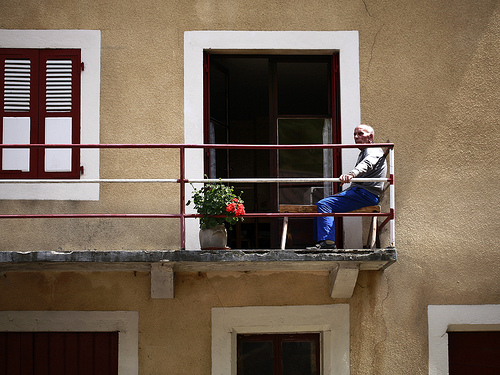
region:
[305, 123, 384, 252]
a seated mean in blue pants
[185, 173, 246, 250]
a potted plant with red flowers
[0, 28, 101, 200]
a red and white window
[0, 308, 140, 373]
the top corner of a door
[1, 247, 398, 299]
the floor of a balcony with supports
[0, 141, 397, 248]
a red and white metal safety railing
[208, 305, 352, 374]
the top of a window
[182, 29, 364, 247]
an open doorway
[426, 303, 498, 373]
the corner of a door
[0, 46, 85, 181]
a closed pair of shutters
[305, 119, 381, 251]
Man sitting on a chair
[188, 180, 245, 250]
The plant is in a pot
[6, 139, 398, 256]
The railing is red and white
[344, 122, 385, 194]
Man wearing a tan jacket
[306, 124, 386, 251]
Man wearing blue jeans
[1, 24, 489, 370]
The windows and door are framed white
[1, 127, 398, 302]
The man is on a balcony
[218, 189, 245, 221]
The flowers are red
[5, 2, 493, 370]
The building has tan walls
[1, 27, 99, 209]
The blinds are brown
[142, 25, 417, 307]
man sitting on balcony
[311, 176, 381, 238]
man wearing blue pants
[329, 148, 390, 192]
man holding on to rail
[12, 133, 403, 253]
balcony rail is burgundy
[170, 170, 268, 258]
potted plant on balcony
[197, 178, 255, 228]
plant has red flowers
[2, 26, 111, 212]
window has red shutters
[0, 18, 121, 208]
window has white frame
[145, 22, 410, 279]
doorway is white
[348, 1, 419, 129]
wall has hair line crack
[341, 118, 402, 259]
man in white shirt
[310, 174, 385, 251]
man in blue jeans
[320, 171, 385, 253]
blue jeans on man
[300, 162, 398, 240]
man sitting on patio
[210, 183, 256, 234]
red flower on plant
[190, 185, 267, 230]
plant with red flower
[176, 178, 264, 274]
plant in gray pot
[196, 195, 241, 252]
gray pot with plant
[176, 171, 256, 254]
green plant in pot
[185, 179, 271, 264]
green plant on patio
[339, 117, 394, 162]
the head of a man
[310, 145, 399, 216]
a man wearing a shirt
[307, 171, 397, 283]
a man wearing pants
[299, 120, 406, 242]
a man sitting down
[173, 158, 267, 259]
a flower in a pot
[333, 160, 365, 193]
the hand of a man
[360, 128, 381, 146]
the ear on a man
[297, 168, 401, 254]
a man with blue jeans on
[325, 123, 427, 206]
a man wearing a long sleeve shirt on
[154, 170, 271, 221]
green leaves on a flower